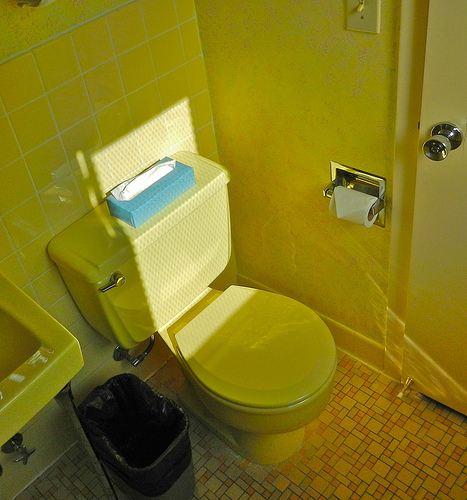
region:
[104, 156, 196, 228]
A blue kleenex box.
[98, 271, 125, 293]
A silver metal flushing lever.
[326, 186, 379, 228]
A roll of toilet paper.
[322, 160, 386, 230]
A silver metal toilet paper dispenser.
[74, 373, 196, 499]
A black garbage can.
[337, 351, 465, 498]
The floor is patterened tile.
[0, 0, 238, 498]
The wall behind the toilet is tile.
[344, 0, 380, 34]
A light switch.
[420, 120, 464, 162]
A silver door handle.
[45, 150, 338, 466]
A toilet with the seat down.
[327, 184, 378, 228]
the toilet paper roll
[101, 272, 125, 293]
the handle on the toilet bowl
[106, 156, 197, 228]
the kleenex box on the toilet tank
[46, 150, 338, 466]
the light colored toilet bowl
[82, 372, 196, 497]
the trash can next to the table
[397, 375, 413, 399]
the door stopper at the bottom of the door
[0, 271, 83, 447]
the sink next to the toilet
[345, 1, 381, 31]
the light switch plate on the wall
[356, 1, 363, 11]
the light switch on the wall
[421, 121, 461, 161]
the door knob on the door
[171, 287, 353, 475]
this is a toilet bowl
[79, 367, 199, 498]
this is a dust bin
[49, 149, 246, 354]
this is a toilet cistern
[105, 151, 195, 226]
this is tissue paper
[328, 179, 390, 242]
a roll of tissue paper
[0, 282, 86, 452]
the edge of a sink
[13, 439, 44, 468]
this is a tap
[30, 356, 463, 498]
the floor is tiled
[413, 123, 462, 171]
this is a tap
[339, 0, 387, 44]
this is a switch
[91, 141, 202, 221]
a napkin box kept above the flush tank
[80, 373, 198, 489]
dustbin kept near the toilet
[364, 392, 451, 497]
floor tiles with the nice design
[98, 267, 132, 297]
flush tank controller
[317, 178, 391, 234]
napkin roll hanging in the wall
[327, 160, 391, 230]
silver color nice hanger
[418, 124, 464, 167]
silve door handle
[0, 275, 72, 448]
sink near the toilet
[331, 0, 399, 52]
switch board attached in the wall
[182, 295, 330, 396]
cover of the toilet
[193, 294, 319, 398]
A lid of a toilet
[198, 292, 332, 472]
A toilet seat in the photo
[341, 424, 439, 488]
A floor with tiles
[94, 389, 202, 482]
A trash can in the photo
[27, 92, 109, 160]
A wall with tiles.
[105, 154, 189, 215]
A paper towel box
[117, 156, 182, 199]
Paper towels in the photo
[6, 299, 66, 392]
a sink in the bathroom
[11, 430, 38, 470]
A tap in the photo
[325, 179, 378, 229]
A toilet paper in the bathroom